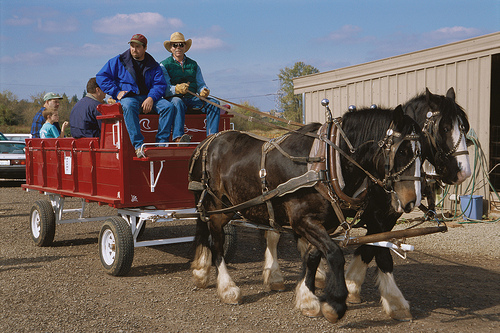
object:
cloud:
[95, 12, 184, 34]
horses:
[187, 99, 426, 322]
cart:
[20, 103, 234, 277]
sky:
[2, 1, 499, 111]